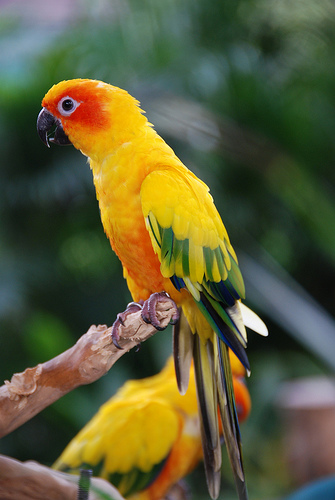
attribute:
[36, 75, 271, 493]
bird — yellow, colorful, perched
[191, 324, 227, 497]
tail feather — black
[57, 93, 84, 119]
eye — open, black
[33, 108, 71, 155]
beak — black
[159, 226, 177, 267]
feather — green, blue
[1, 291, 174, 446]
perch — brown, small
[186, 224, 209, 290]
feather — yellow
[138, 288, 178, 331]
foot — black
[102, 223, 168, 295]
belly — orange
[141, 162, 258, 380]
wing — green, yellow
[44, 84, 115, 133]
patch — orange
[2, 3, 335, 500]
tree — green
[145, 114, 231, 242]
back — yellow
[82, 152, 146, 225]
breast — yellow